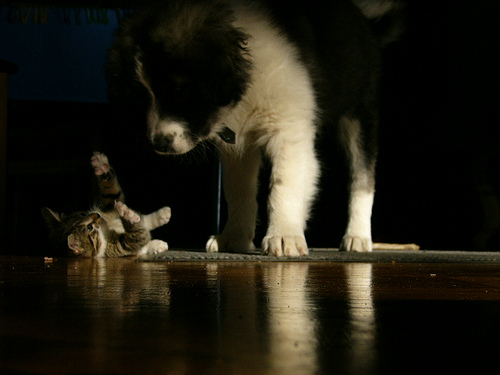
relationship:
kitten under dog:
[41, 137, 157, 273] [114, 10, 461, 250]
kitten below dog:
[41, 137, 157, 273] [114, 10, 461, 250]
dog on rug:
[114, 10, 461, 250] [135, 220, 496, 274]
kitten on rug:
[41, 137, 157, 273] [135, 220, 496, 274]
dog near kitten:
[114, 10, 461, 250] [41, 137, 157, 273]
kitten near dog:
[41, 137, 157, 273] [114, 10, 461, 250]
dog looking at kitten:
[114, 10, 461, 250] [41, 169, 202, 282]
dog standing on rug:
[114, 10, 461, 250] [183, 246, 450, 273]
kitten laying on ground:
[41, 137, 157, 273] [2, 250, 474, 371]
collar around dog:
[207, 123, 240, 148] [125, 1, 388, 260]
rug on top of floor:
[149, 248, 483, 263] [2, 249, 481, 372]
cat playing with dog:
[36, 149, 175, 266] [132, 0, 422, 265]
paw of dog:
[259, 229, 313, 259] [125, 1, 388, 260]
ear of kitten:
[42, 205, 68, 229] [43, 146, 180, 269]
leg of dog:
[259, 103, 324, 258] [125, 1, 388, 260]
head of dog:
[132, 1, 254, 162] [125, 1, 388, 260]